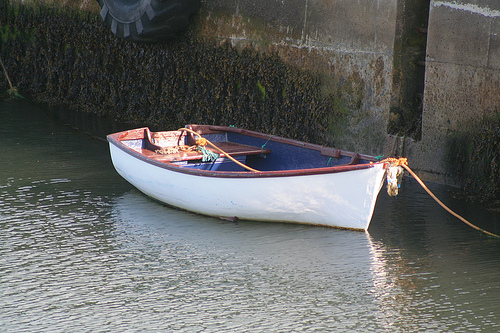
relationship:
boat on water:
[106, 123, 393, 232] [0, 99, 498, 332]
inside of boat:
[123, 132, 375, 173] [106, 123, 393, 232]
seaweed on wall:
[1, 1, 325, 145] [1, 3, 497, 198]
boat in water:
[106, 123, 393, 232] [0, 99, 498, 332]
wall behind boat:
[1, 3, 497, 198] [106, 123, 393, 232]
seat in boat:
[130, 140, 269, 164] [106, 123, 393, 232]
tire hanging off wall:
[95, 0, 201, 42] [1, 3, 497, 198]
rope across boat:
[175, 127, 499, 240] [106, 123, 393, 232]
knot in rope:
[197, 136, 206, 147] [175, 127, 499, 240]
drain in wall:
[386, 1, 433, 143] [1, 3, 497, 198]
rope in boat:
[177, 126, 265, 175] [106, 123, 393, 232]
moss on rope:
[475, 224, 499, 240] [393, 157, 499, 244]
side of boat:
[109, 144, 388, 232] [106, 123, 393, 232]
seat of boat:
[130, 140, 269, 164] [106, 123, 393, 232]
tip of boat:
[363, 152, 393, 232] [106, 123, 393, 232]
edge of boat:
[106, 124, 389, 178] [106, 123, 393, 232]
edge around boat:
[106, 124, 389, 178] [106, 123, 393, 232]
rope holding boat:
[175, 127, 499, 240] [106, 123, 393, 232]